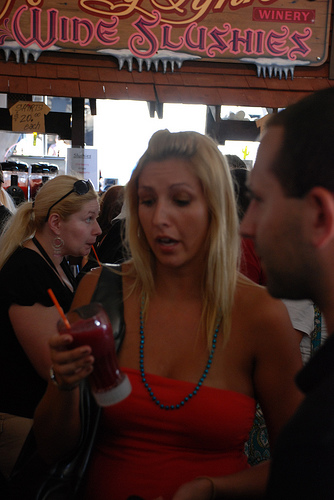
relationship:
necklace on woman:
[130, 261, 225, 411] [42, 127, 314, 477]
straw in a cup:
[45, 289, 73, 327] [57, 298, 134, 411]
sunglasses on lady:
[43, 179, 96, 221] [0, 166, 103, 457]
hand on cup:
[44, 326, 97, 395] [57, 298, 134, 411]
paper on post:
[61, 142, 103, 193] [69, 92, 83, 153]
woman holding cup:
[42, 127, 314, 477] [57, 298, 134, 411]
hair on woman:
[118, 118, 244, 344] [42, 127, 314, 477]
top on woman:
[77, 370, 266, 499] [42, 127, 314, 477]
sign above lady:
[2, 0, 329, 70] [0, 166, 103, 457]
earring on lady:
[48, 235, 67, 256] [0, 166, 103, 457]